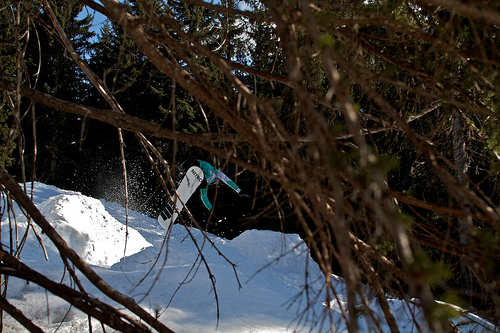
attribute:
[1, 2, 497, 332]
tree — wood, tall, thick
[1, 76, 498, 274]
branch — wooden, leafless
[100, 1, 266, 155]
branch — wooden, leafless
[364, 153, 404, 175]
leaf — green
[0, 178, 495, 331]
snow — white, hill, small, surface, landscape, pile, ground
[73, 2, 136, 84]
sky — blue, clear blue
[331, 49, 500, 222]
branch — wooden, leafless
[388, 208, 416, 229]
leaf — green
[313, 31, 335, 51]
leaf — green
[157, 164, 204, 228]
snowboard — white, black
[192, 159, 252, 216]
snowboarder — jumping, tricking, snowboarding, mid air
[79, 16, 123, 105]
pine tree — large, green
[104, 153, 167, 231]
snow — mid air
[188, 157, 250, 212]
suit — green, black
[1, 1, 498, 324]
forest — winter season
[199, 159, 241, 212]
jacket — green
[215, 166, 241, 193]
arm — up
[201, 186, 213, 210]
arm — up